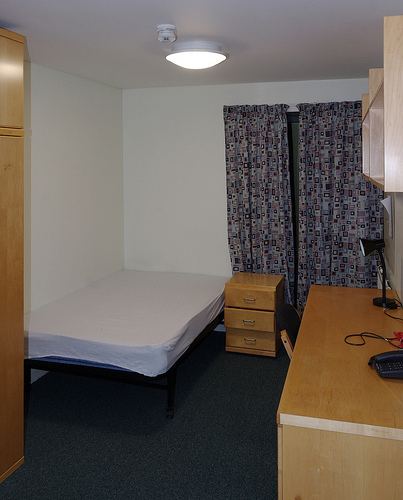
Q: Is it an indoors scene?
A: Yes, it is indoors.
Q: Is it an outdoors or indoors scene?
A: It is indoors.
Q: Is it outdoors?
A: No, it is indoors.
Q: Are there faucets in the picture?
A: No, there are no faucets.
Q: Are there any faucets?
A: No, there are no faucets.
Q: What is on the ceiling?
A: The ceiling light is on the ceiling.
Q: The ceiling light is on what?
A: The ceiling light is on the ceiling.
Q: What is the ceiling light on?
A: The ceiling light is on the ceiling.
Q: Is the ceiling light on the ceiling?
A: Yes, the ceiling light is on the ceiling.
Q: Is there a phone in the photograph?
A: Yes, there is a phone.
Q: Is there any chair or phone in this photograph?
A: Yes, there is a phone.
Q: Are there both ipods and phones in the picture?
A: No, there is a phone but no ipods.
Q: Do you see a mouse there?
A: No, there are no computer mice.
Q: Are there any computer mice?
A: No, there are no computer mice.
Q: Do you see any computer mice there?
A: No, there are no computer mice.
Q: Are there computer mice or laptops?
A: No, there are no computer mice or laptops.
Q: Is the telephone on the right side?
A: Yes, the telephone is on the right of the image.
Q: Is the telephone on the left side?
A: No, the telephone is on the right of the image.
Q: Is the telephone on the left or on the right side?
A: The telephone is on the right of the image.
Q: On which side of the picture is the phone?
A: The phone is on the right of the image.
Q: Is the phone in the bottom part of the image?
A: Yes, the phone is in the bottom of the image.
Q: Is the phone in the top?
A: No, the phone is in the bottom of the image.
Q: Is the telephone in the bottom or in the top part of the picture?
A: The telephone is in the bottom of the image.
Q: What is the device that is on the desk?
A: The device is a phone.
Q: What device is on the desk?
A: The device is a phone.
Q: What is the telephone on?
A: The telephone is on the desk.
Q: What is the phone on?
A: The telephone is on the desk.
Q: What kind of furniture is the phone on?
A: The phone is on the desk.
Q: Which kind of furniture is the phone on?
A: The phone is on the desk.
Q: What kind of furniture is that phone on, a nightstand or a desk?
A: The phone is on a desk.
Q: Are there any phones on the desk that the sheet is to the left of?
A: Yes, there is a phone on the desk.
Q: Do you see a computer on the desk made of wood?
A: No, there is a phone on the desk.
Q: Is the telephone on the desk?
A: Yes, the telephone is on the desk.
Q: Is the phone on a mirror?
A: No, the phone is on the desk.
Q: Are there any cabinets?
A: Yes, there is a cabinet.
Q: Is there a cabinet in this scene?
A: Yes, there is a cabinet.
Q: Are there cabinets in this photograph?
A: Yes, there is a cabinet.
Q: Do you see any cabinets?
A: Yes, there is a cabinet.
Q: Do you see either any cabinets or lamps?
A: Yes, there is a cabinet.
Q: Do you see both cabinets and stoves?
A: No, there is a cabinet but no stoves.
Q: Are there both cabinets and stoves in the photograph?
A: No, there is a cabinet but no stoves.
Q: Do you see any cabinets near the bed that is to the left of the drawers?
A: Yes, there is a cabinet near the bed.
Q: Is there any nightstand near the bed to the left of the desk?
A: No, there is a cabinet near the bed.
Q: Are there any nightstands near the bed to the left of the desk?
A: No, there is a cabinet near the bed.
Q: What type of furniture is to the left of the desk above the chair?
A: The piece of furniture is a cabinet.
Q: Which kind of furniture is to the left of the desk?
A: The piece of furniture is a cabinet.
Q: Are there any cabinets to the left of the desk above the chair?
A: Yes, there is a cabinet to the left of the desk.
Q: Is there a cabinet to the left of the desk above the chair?
A: Yes, there is a cabinet to the left of the desk.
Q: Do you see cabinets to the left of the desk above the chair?
A: Yes, there is a cabinet to the left of the desk.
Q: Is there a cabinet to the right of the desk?
A: No, the cabinet is to the left of the desk.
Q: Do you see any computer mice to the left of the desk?
A: No, there is a cabinet to the left of the desk.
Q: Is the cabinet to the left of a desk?
A: Yes, the cabinet is to the left of a desk.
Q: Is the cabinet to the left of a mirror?
A: No, the cabinet is to the left of a desk.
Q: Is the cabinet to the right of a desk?
A: No, the cabinet is to the left of a desk.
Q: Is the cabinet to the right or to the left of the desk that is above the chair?
A: The cabinet is to the left of the desk.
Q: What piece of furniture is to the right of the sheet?
A: The piece of furniture is a cabinet.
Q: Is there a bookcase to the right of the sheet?
A: No, there is a cabinet to the right of the sheet.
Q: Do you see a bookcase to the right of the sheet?
A: No, there is a cabinet to the right of the sheet.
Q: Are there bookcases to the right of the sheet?
A: No, there is a cabinet to the right of the sheet.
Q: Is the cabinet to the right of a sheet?
A: Yes, the cabinet is to the right of a sheet.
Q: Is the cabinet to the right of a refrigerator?
A: No, the cabinet is to the right of a sheet.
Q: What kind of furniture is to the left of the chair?
A: The piece of furniture is a cabinet.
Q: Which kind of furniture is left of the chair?
A: The piece of furniture is a cabinet.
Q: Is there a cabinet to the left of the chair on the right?
A: Yes, there is a cabinet to the left of the chair.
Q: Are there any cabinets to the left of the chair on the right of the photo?
A: Yes, there is a cabinet to the left of the chair.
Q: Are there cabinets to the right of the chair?
A: No, the cabinet is to the left of the chair.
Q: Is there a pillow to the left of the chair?
A: No, there is a cabinet to the left of the chair.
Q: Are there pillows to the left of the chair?
A: No, there is a cabinet to the left of the chair.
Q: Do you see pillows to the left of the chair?
A: No, there is a cabinet to the left of the chair.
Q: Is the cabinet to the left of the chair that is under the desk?
A: Yes, the cabinet is to the left of the chair.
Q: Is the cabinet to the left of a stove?
A: No, the cabinet is to the left of the chair.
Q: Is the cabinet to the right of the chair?
A: No, the cabinet is to the left of the chair.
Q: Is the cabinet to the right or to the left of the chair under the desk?
A: The cabinet is to the left of the chair.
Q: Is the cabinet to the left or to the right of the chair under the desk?
A: The cabinet is to the left of the chair.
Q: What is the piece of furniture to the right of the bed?
A: The piece of furniture is a cabinet.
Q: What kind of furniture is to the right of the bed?
A: The piece of furniture is a cabinet.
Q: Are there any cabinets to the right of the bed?
A: Yes, there is a cabinet to the right of the bed.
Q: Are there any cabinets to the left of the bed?
A: No, the cabinet is to the right of the bed.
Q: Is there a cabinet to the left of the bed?
A: No, the cabinet is to the right of the bed.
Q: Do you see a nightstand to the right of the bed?
A: No, there is a cabinet to the right of the bed.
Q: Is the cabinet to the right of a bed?
A: Yes, the cabinet is to the right of a bed.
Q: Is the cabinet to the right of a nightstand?
A: No, the cabinet is to the right of a bed.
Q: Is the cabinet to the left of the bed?
A: No, the cabinet is to the right of the bed.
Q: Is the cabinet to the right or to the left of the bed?
A: The cabinet is to the right of the bed.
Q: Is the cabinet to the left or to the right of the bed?
A: The cabinet is to the right of the bed.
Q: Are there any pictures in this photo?
A: No, there are no pictures.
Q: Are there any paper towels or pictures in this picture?
A: No, there are no pictures or paper towels.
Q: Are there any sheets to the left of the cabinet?
A: Yes, there is a sheet to the left of the cabinet.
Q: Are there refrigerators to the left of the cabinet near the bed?
A: No, there is a sheet to the left of the cabinet.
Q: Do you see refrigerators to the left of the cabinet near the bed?
A: No, there is a sheet to the left of the cabinet.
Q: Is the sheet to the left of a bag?
A: No, the sheet is to the left of a cabinet.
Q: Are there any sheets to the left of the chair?
A: Yes, there is a sheet to the left of the chair.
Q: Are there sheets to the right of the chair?
A: No, the sheet is to the left of the chair.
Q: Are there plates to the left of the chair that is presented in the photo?
A: No, there is a sheet to the left of the chair.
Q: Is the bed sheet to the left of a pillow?
A: No, the bed sheet is to the left of the chair.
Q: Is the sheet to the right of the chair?
A: No, the sheet is to the left of the chair.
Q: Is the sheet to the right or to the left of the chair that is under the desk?
A: The sheet is to the left of the chair.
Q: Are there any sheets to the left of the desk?
A: Yes, there is a sheet to the left of the desk.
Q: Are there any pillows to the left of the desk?
A: No, there is a sheet to the left of the desk.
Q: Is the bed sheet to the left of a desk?
A: Yes, the bed sheet is to the left of a desk.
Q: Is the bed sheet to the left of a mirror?
A: No, the bed sheet is to the left of a desk.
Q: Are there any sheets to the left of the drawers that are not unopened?
A: Yes, there is a sheet to the left of the drawers.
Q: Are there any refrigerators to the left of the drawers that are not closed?
A: No, there is a sheet to the left of the drawers.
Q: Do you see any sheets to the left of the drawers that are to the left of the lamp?
A: Yes, there is a sheet to the left of the drawers.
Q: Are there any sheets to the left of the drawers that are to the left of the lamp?
A: Yes, there is a sheet to the left of the drawers.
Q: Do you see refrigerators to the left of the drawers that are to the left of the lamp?
A: No, there is a sheet to the left of the drawers.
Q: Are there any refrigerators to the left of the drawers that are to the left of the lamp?
A: No, there is a sheet to the left of the drawers.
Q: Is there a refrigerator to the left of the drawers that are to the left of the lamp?
A: No, there is a sheet to the left of the drawers.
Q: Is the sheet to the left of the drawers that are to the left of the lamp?
A: Yes, the sheet is to the left of the drawers.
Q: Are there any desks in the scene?
A: Yes, there is a desk.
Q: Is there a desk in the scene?
A: Yes, there is a desk.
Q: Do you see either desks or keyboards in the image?
A: Yes, there is a desk.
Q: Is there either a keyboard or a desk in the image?
A: Yes, there is a desk.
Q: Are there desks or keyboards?
A: Yes, there is a desk.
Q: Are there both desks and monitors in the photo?
A: No, there is a desk but no monitors.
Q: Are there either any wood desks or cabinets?
A: Yes, there is a wood desk.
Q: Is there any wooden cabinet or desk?
A: Yes, there is a wood desk.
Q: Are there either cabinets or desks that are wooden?
A: Yes, the desk is wooden.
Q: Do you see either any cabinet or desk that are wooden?
A: Yes, the desk is wooden.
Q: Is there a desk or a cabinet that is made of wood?
A: Yes, the desk is made of wood.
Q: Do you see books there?
A: No, there are no books.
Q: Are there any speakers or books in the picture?
A: No, there are no books or speakers.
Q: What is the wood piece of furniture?
A: The piece of furniture is a desk.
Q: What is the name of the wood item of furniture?
A: The piece of furniture is a desk.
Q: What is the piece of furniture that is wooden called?
A: The piece of furniture is a desk.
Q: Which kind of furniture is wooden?
A: The furniture is a desk.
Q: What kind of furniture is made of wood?
A: The furniture is a desk.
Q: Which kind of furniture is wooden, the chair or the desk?
A: The desk is wooden.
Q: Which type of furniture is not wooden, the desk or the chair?
A: The chair is not wooden.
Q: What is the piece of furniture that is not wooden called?
A: The piece of furniture is a chair.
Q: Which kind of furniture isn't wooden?
A: The furniture is a chair.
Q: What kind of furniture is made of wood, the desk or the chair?
A: The desk is made of wood.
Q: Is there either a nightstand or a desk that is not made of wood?
A: No, there is a desk but it is made of wood.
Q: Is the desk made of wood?
A: Yes, the desk is made of wood.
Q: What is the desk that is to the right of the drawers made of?
A: The desk is made of wood.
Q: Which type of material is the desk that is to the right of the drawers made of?
A: The desk is made of wood.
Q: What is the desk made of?
A: The desk is made of wood.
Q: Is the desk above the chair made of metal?
A: No, the desk is made of wood.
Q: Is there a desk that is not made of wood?
A: No, there is a desk but it is made of wood.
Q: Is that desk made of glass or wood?
A: The desk is made of wood.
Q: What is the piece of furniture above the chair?
A: The piece of furniture is a desk.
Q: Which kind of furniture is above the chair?
A: The piece of furniture is a desk.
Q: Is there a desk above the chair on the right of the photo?
A: Yes, there is a desk above the chair.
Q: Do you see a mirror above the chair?
A: No, there is a desk above the chair.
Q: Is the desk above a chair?
A: Yes, the desk is above a chair.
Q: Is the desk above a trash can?
A: No, the desk is above a chair.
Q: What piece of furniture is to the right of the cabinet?
A: The piece of furniture is a desk.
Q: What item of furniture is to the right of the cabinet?
A: The piece of furniture is a desk.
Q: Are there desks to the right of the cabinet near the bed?
A: Yes, there is a desk to the right of the cabinet.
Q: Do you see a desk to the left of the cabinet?
A: No, the desk is to the right of the cabinet.